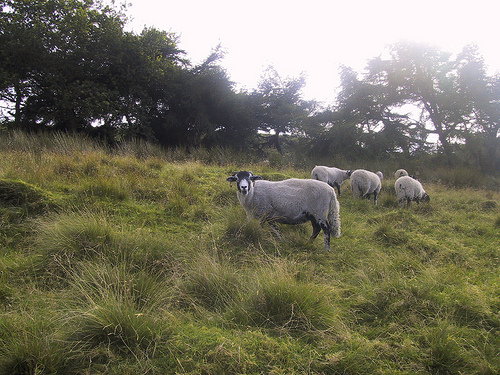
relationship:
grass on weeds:
[5, 258, 483, 374] [5, 252, 494, 372]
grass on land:
[5, 258, 483, 374] [0, 157, 499, 373]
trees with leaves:
[154, 39, 368, 155] [265, 78, 320, 135]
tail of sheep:
[327, 188, 349, 236] [311, 165, 354, 196]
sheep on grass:
[311, 165, 354, 196] [0, 123, 484, 350]